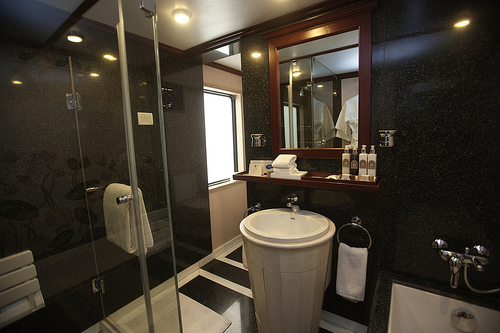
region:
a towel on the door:
[97, 179, 162, 259]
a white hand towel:
[336, 240, 370, 305]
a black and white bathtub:
[368, 259, 499, 332]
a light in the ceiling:
[171, 7, 191, 28]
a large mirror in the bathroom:
[265, 24, 370, 156]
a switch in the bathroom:
[135, 108, 156, 127]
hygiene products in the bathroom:
[340, 142, 377, 179]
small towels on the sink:
[270, 153, 300, 173]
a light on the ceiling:
[63, 29, 83, 44]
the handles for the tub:
[430, 237, 492, 297]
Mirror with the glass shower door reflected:
[267, 10, 373, 161]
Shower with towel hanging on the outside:
[0, 1, 185, 331]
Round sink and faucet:
[239, 189, 336, 330]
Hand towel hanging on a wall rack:
[336, 213, 373, 312]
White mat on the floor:
[104, 283, 232, 332]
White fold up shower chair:
[0, 248, 48, 328]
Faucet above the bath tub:
[374, 236, 499, 329]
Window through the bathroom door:
[196, 34, 251, 267]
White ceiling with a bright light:
[81, 0, 334, 55]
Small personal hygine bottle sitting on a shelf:
[367, 143, 383, 175]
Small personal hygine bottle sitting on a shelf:
[356, 144, 368, 171]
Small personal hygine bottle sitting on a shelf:
[350, 144, 363, 174]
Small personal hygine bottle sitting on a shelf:
[337, 140, 353, 172]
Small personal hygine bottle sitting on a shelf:
[353, 171, 378, 183]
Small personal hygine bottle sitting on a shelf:
[336, 168, 357, 182]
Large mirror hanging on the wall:
[256, 23, 382, 163]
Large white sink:
[225, 198, 337, 332]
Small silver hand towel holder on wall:
[333, 208, 378, 305]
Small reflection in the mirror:
[280, 51, 351, 148]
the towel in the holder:
[327, 234, 370, 311]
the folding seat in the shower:
[2, 248, 61, 321]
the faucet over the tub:
[435, 231, 487, 301]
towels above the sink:
[267, 151, 307, 177]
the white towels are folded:
[272, 149, 302, 174]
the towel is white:
[331, 238, 371, 305]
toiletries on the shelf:
[335, 138, 383, 182]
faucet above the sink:
[277, 190, 307, 212]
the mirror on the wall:
[257, 32, 386, 154]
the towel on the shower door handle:
[95, 186, 160, 257]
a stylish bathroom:
[6, 12, 491, 322]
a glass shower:
[3, 2, 188, 327]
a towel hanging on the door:
[101, 176, 146, 251]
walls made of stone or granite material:
[235, 6, 487, 291]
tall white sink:
[238, 201, 328, 328]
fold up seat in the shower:
[0, 243, 58, 318]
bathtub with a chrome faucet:
[390, 220, 496, 330]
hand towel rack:
[338, 208, 368, 301]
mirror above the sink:
[261, 17, 366, 162]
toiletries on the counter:
[318, 142, 378, 183]